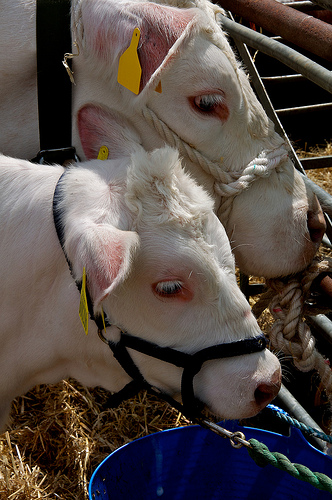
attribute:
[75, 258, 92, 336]
tag — yellow and black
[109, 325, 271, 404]
straps — black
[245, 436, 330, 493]
rope — green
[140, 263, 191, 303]
eyelashes — white 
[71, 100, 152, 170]
ear — white 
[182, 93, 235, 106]
eyelashes — white 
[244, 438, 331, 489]
rope — green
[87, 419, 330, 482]
bucket — blue 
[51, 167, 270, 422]
strap — black 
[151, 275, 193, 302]
ring — pink 